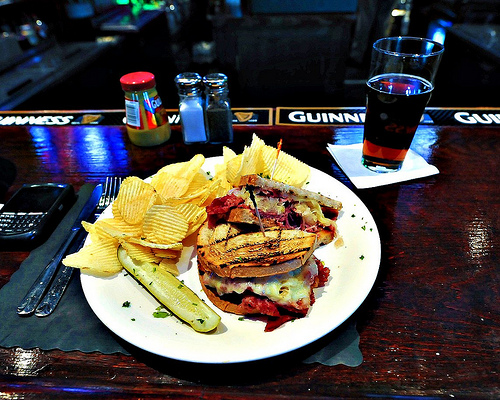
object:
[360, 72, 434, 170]
beverage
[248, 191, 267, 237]
toothpick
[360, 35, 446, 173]
drink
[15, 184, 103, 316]
knife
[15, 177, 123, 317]
fork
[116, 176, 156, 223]
chip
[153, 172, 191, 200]
chip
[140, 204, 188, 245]
chip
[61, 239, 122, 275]
chip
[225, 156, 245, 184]
chip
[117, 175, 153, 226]
bunch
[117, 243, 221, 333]
pickle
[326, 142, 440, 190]
napkin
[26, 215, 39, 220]
buttons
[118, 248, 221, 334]
food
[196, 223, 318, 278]
food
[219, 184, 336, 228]
food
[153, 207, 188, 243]
food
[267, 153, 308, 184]
food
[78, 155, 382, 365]
plate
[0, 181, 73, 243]
cell phone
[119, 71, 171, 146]
condiment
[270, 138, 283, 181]
toothpick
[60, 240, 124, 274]
potato chips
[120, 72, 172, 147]
mustard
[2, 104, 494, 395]
table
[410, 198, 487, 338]
carpet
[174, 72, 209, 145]
salt shaker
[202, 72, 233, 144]
pepper shaker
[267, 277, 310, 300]
cheese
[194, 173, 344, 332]
sandwich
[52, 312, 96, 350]
place mat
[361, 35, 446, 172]
glass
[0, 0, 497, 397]
bar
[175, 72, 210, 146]
shaker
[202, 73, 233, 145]
shaker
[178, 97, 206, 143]
salt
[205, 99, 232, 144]
pepper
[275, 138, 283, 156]
top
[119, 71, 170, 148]
jar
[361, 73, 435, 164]
liquid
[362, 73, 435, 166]
soda